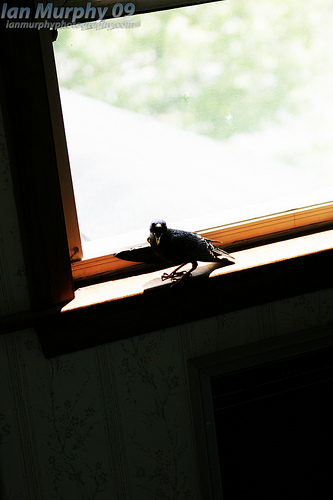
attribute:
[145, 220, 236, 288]
bird — sitting, black, snall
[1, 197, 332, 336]
sill — brown, wood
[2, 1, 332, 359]
window — wood framed, framed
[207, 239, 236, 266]
tail — feathered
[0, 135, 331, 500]
wallpaper — printed, patterned, white, floral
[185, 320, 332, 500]
vent — metal, large, square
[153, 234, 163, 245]
beak — yellow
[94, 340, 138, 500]
line — vertical, tan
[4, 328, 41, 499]
line — vertical, tan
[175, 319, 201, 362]
line — vertical, tan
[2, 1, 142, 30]
wording — ian murphy label, blue, in upper corner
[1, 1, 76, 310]
frame — wooden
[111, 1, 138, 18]
09 — blue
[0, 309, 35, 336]
chair rail — on left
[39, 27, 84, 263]
frame — metal